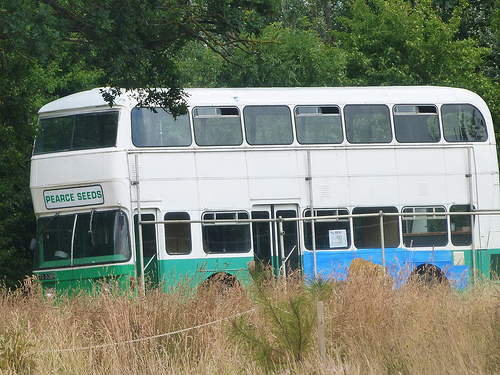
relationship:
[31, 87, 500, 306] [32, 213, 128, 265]
bus has windshield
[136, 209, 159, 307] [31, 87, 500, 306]
door on bus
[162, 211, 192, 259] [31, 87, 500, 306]
window of bus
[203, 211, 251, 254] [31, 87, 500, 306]
window of bus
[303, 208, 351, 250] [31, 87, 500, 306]
window of bus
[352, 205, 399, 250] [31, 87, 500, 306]
window of bus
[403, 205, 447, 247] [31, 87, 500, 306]
window of bus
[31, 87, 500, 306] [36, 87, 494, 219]
bus has levels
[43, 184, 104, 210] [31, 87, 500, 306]
letters on bus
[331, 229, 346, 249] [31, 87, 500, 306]
object on bus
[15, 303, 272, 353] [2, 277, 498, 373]
wire in grass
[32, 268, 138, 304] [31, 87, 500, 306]
bumper on bus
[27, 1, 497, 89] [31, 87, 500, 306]
trees behind bus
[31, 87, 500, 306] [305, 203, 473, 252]
bus has windows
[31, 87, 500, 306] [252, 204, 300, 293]
bus has door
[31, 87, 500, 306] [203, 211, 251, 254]
bus has window